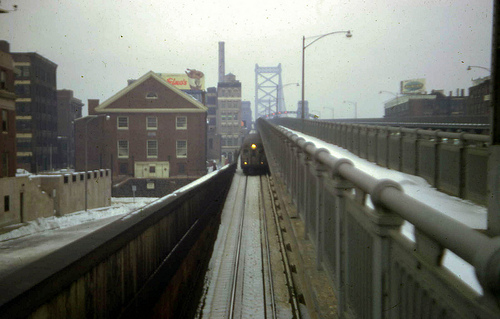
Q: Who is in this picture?
A: Noone.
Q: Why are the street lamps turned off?
A: It is daytime.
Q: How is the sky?
A: Overcast.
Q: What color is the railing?
A: Grey.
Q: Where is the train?
A: On the tracks.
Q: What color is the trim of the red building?
A: Yellow.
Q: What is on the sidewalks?
A: Snow.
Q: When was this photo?
A: Daytime.